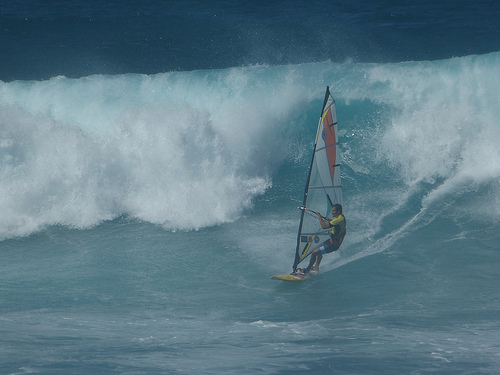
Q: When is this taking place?
A: Daytime.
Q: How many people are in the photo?
A: One.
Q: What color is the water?
A: Blue and white.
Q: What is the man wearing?
A: Wetsuit.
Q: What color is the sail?
A: Red and white.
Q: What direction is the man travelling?
A: Downward.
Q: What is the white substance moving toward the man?
A: Wave.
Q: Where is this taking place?
A: Ocean.